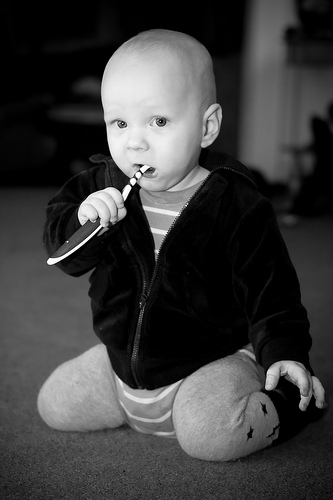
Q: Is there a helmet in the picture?
A: No, there are no helmets.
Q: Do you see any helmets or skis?
A: No, there are no helmets or skis.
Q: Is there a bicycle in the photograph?
A: No, there are no bicycles.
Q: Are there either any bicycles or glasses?
A: No, there are no bicycles or glasses.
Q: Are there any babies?
A: Yes, there is a baby.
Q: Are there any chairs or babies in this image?
A: Yes, there is a baby.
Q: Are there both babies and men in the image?
A: No, there is a baby but no men.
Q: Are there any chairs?
A: No, there are no chairs.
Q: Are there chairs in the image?
A: No, there are no chairs.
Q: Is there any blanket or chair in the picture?
A: No, there are no chairs or blankets.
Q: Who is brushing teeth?
A: The baby is brushing teeth.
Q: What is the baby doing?
A: The baby is brushing teeth.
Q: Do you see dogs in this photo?
A: No, there are no dogs.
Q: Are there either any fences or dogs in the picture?
A: No, there are no dogs or fences.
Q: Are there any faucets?
A: No, there are no faucets.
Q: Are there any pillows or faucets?
A: No, there are no faucets or pillows.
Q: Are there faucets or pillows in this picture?
A: No, there are no faucets or pillows.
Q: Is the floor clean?
A: Yes, the floor is clean.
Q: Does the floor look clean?
A: Yes, the floor is clean.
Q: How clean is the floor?
A: The floor is clean.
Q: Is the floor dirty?
A: No, the floor is clean.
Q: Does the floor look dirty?
A: No, the floor is clean.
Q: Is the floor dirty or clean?
A: The floor is clean.